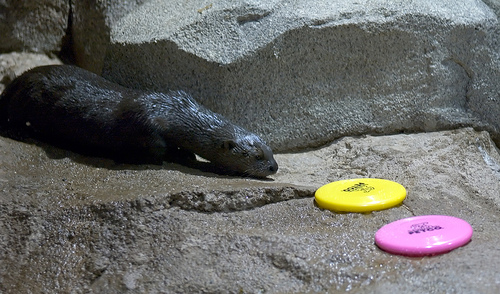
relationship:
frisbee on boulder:
[373, 213, 472, 256] [233, 14, 480, 151]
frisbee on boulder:
[313, 177, 408, 213] [404, 140, 492, 200]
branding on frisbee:
[344, 177, 368, 193] [313, 177, 408, 213]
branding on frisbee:
[404, 219, 445, 236] [373, 213, 472, 256]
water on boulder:
[15, 119, 328, 290] [3, 127, 495, 291]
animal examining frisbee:
[0, 64, 279, 178] [313, 176, 408, 213]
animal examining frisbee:
[0, 64, 279, 178] [373, 213, 472, 256]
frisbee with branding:
[313, 177, 408, 213] [341, 182, 375, 193]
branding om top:
[341, 182, 375, 193] [316, 176, 406, 209]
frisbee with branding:
[373, 213, 472, 256] [407, 221, 443, 234]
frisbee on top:
[373, 213, 472, 256] [374, 215, 471, 251]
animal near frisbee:
[0, 64, 279, 178] [320, 170, 418, 215]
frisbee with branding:
[313, 177, 408, 213] [407, 221, 443, 234]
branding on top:
[341, 182, 375, 193] [315, 177, 401, 205]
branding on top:
[407, 221, 443, 234] [377, 214, 467, 253]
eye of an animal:
[237, 151, 275, 166] [0, 64, 279, 178]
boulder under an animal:
[0, 126, 499, 292] [0, 64, 279, 178]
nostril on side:
[267, 163, 274, 170] [228, 151, 275, 175]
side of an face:
[228, 151, 275, 175] [245, 141, 278, 181]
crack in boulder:
[127, 180, 321, 220] [69, 1, 499, 153]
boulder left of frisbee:
[69, 1, 499, 153] [310, 172, 412, 215]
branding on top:
[407, 221, 443, 234] [375, 215, 468, 248]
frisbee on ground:
[313, 177, 408, 213] [5, 131, 496, 287]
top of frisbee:
[315, 177, 406, 206] [313, 177, 408, 213]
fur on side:
[60, 77, 110, 125] [0, 84, 214, 162]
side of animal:
[0, 84, 214, 162] [0, 63, 279, 179]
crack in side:
[452, 53, 478, 118] [231, 17, 497, 154]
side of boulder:
[231, 17, 497, 154] [67, 1, 499, 153]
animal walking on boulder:
[0, 63, 279, 179] [69, 1, 499, 153]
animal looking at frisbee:
[0, 64, 279, 178] [313, 168, 413, 215]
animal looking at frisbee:
[0, 64, 279, 178] [373, 213, 472, 256]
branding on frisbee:
[407, 221, 443, 234] [377, 200, 477, 262]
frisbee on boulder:
[313, 176, 408, 213] [69, 1, 499, 153]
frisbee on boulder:
[373, 213, 472, 256] [69, 1, 499, 153]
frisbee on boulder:
[313, 176, 408, 213] [0, 126, 499, 292]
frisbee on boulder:
[373, 213, 472, 256] [0, 126, 499, 292]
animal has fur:
[0, 64, 279, 178] [60, 77, 110, 125]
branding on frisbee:
[341, 182, 375, 193] [313, 176, 408, 213]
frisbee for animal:
[313, 177, 408, 213] [0, 64, 279, 178]